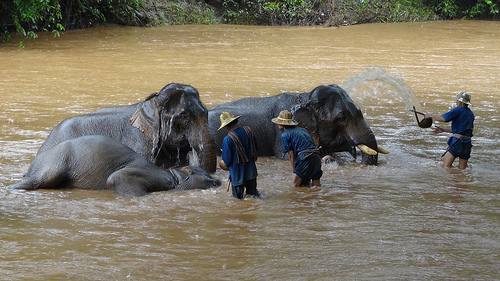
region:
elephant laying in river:
[18, 135, 222, 233]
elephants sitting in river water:
[45, 91, 398, 174]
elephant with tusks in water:
[221, 80, 407, 180]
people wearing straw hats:
[210, 85, 495, 188]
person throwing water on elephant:
[311, 63, 489, 180]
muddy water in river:
[13, 39, 494, 236]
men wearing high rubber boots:
[272, 93, 491, 192]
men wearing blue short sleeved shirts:
[276, 95, 493, 189]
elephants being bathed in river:
[11, 66, 496, 243]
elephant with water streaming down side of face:
[35, 82, 245, 202]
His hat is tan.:
[218, 101, 242, 126]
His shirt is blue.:
[208, 128, 263, 186]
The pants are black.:
[228, 178, 259, 207]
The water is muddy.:
[24, 28, 490, 278]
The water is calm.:
[10, 30, 496, 273]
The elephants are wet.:
[39, 78, 213, 211]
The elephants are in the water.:
[22, 60, 385, 213]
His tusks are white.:
[356, 133, 391, 159]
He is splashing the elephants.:
[336, 53, 496, 155]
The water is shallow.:
[4, 13, 456, 278]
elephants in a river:
[36, 84, 396, 199]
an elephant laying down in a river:
[7, 134, 222, 199]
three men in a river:
[214, 92, 476, 194]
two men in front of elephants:
[81, 77, 324, 188]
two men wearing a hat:
[210, 108, 322, 193]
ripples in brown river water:
[41, 199, 478, 276]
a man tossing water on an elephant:
[343, 71, 477, 174]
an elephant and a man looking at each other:
[50, 82, 327, 190]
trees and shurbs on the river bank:
[0, 0, 498, 40]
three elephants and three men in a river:
[30, 85, 477, 191]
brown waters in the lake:
[125, 44, 254, 71]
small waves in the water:
[385, 141, 440, 181]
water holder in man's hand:
[396, 97, 435, 134]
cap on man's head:
[440, 84, 478, 113]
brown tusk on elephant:
[353, 140, 387, 161]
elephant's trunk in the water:
[343, 153, 389, 172]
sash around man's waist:
[273, 140, 352, 167]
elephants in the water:
[34, 94, 369, 214]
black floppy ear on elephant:
[120, 89, 171, 153]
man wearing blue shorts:
[440, 128, 491, 167]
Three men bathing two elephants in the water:
[10, 68, 485, 202]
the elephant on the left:
[8, 133, 219, 198]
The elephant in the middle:
[26, 77, 220, 173]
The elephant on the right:
[202, 79, 392, 165]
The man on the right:
[206, 106, 271, 203]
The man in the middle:
[265, 108, 337, 192]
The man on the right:
[425, 88, 481, 177]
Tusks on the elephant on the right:
[353, 136, 392, 159]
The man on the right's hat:
[450, 90, 474, 110]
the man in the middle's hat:
[268, 106, 299, 131]